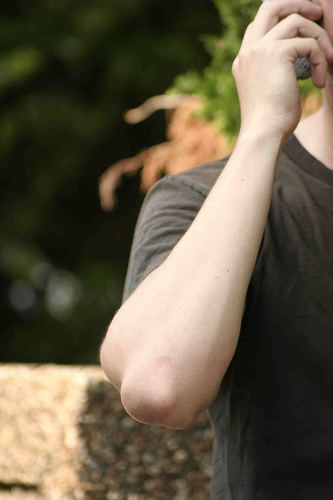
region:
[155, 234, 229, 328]
A hand in the photo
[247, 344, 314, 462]
A t-shirt in the photo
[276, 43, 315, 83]
A phone in the hand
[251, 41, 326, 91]
A cellphone in the photo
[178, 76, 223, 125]
Trees at the back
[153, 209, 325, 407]
A man in the picture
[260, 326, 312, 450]
Black t-shirt in the picture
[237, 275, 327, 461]
A man standing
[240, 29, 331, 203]
A man making a call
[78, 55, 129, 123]
Trees at the back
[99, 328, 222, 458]
this is an elbow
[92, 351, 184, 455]
the funny bone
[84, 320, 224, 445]
a guy's right elbow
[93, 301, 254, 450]
this is someone's elbow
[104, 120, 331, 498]
a grey tee shirt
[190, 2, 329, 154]
this is a hand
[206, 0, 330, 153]
the hand is holding a phone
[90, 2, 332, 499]
this person is wearing a tee shirt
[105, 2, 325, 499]
this person is holding a phone to his face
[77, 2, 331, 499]
his arm is bent at the elbow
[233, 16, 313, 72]
Person holding a cellphone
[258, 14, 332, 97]
Person holding a cellphone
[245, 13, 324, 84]
Person holding a cellphone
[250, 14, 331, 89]
Person holding a cellphone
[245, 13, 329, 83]
Person holding a cellphone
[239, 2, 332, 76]
Person holding a cellphone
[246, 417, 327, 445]
person wearing a black shirt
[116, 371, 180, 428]
man's elbow sticking out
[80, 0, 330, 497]
man talking on cell phone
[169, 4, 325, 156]
green fern behind man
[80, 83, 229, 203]
orange spindly plant behind man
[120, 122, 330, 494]
black cotton t-shirt on man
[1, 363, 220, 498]
gravel and concrete wall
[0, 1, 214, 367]
blurred trees in background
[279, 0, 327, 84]
ear bud in man's ear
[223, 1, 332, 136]
man's hand with curled fingers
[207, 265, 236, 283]
two moles on man's arm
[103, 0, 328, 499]
a person speaking on a phone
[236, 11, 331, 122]
cellphone in person's right hand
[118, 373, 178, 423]
the person's right elbow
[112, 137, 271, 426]
the person's forearm.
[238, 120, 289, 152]
the person's right wrist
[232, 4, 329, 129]
the person's right hand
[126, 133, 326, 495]
a brown t-shirt on the man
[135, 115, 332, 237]
the man's shoulder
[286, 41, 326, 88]
the man's right pinkie finger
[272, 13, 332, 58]
the right ring finger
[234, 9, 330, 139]
Hand holding cell phone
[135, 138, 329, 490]
Man wearing black shirt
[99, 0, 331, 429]
A white person's arm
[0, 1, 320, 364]
The dark vegetation in the background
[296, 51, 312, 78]
A partially blocked cellphone.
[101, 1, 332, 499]
The person wearing a gray t-shirt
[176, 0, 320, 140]
The green faded bushes in the background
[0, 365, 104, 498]
The lighted faded space on the left.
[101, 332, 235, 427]
The folded elbow of a man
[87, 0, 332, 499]
The light skinned arm.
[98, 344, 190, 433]
bony elbow of white boy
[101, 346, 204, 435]
bony elbow of white boy